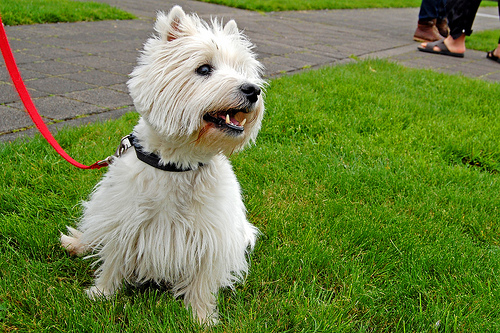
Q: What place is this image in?
A: It is at the sidewalk.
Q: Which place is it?
A: It is a sidewalk.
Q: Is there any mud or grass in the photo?
A: Yes, there is grass.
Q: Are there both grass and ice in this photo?
A: No, there is grass but no ice.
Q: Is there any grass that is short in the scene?
A: Yes, there is short grass.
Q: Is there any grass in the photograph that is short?
A: Yes, there is grass that is short.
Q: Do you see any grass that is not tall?
A: Yes, there is short grass.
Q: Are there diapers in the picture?
A: No, there are no diapers.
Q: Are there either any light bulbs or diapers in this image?
A: No, there are no diapers or light bulbs.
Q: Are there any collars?
A: Yes, there is a collar.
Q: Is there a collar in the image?
A: Yes, there is a collar.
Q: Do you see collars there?
A: Yes, there is a collar.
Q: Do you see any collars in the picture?
A: Yes, there is a collar.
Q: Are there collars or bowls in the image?
A: Yes, there is a collar.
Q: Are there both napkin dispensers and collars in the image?
A: No, there is a collar but no napkin dispensers.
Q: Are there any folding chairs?
A: No, there are no folding chairs.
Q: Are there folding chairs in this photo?
A: No, there are no folding chairs.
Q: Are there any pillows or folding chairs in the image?
A: No, there are no folding chairs or pillows.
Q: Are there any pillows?
A: No, there are no pillows.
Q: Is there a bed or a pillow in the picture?
A: No, there are no pillows or beds.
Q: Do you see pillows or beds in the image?
A: No, there are no pillows or beds.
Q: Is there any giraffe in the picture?
A: No, there are no giraffes.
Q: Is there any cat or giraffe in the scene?
A: No, there are no giraffes or cats.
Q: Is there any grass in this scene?
A: Yes, there is grass.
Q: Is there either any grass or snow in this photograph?
A: Yes, there is grass.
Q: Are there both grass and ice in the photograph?
A: No, there is grass but no ice.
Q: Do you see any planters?
A: No, there are no planters.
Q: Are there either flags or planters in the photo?
A: No, there are no planters or flags.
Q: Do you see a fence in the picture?
A: No, there are no fences.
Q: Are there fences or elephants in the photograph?
A: No, there are no fences or elephants.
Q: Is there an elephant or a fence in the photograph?
A: No, there are no fences or elephants.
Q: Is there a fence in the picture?
A: No, there are no fences.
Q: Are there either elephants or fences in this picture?
A: No, there are no fences or elephants.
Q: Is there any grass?
A: Yes, there is grass.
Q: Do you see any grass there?
A: Yes, there is grass.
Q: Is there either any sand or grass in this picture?
A: Yes, there is grass.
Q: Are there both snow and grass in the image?
A: No, there is grass but no snow.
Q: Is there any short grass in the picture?
A: Yes, there is short grass.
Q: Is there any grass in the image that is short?
A: Yes, there is grass that is short.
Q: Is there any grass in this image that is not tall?
A: Yes, there is short grass.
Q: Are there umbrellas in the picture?
A: No, there are no umbrellas.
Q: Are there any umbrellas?
A: No, there are no umbrellas.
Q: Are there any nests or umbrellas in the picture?
A: No, there are no umbrellas or nests.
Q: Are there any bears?
A: No, there are no bears.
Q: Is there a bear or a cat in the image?
A: No, there are no bears or cats.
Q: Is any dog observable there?
A: Yes, there is a dog.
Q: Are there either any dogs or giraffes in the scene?
A: Yes, there is a dog.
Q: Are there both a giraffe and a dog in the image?
A: No, there is a dog but no giraffes.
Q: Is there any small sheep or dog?
A: Yes, there is a small dog.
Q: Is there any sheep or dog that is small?
A: Yes, the dog is small.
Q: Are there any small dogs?
A: Yes, there is a small dog.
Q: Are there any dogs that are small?
A: Yes, there is a dog that is small.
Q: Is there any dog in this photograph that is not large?
A: Yes, there is a small dog.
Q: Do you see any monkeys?
A: No, there are no monkeys.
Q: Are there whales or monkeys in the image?
A: No, there are no monkeys or whales.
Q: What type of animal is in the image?
A: The animal is a dog.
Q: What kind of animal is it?
A: The animal is a dog.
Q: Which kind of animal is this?
A: This is a dog.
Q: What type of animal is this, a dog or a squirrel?
A: This is a dog.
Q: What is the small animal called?
A: The animal is a dog.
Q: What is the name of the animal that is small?
A: The animal is a dog.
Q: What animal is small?
A: The animal is a dog.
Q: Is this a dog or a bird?
A: This is a dog.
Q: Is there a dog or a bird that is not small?
A: No, there is a dog but it is small.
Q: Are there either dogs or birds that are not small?
A: No, there is a dog but it is small.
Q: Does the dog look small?
A: Yes, the dog is small.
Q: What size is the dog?
A: The dog is small.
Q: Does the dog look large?
A: No, the dog is small.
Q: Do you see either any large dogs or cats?
A: No, there is a dog but it is small.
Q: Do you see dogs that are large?
A: No, there is a dog but it is small.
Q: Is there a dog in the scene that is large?
A: No, there is a dog but it is small.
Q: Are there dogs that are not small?
A: No, there is a dog but it is small.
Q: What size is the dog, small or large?
A: The dog is small.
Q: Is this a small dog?
A: Yes, this is a small dog.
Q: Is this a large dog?
A: No, this is a small dog.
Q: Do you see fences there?
A: No, there are no fences.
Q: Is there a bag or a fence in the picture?
A: No, there are no fences or bags.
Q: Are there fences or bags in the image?
A: No, there are no fences or bags.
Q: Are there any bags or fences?
A: No, there are no fences or bags.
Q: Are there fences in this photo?
A: No, there are no fences.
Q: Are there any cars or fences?
A: No, there are no fences or cars.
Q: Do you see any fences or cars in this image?
A: No, there are no fences or cars.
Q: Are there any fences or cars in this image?
A: No, there are no fences or cars.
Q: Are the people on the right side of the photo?
A: Yes, the people are on the right of the image.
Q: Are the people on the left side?
A: No, the people are on the right of the image.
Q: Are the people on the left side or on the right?
A: The people are on the right of the image.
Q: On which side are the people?
A: The people are on the right of the image.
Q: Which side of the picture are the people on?
A: The people are on the right of the image.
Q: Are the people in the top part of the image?
A: Yes, the people are in the top of the image.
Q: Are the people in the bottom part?
A: No, the people are in the top of the image.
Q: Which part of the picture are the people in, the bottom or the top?
A: The people are in the top of the image.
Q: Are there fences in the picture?
A: No, there are no fences.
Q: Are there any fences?
A: No, there are no fences.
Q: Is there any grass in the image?
A: Yes, there is grass.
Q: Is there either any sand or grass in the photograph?
A: Yes, there is grass.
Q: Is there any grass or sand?
A: Yes, there is grass.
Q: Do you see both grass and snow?
A: No, there is grass but no snow.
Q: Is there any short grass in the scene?
A: Yes, there is short grass.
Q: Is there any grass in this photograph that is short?
A: Yes, there is grass that is short.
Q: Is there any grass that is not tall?
A: Yes, there is short grass.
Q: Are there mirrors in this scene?
A: No, there are no mirrors.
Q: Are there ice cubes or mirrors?
A: No, there are no mirrors or ice cubes.